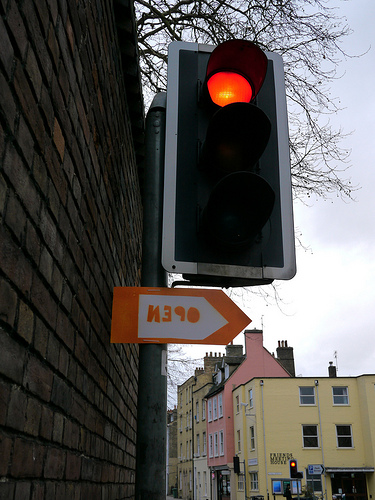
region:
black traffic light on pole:
[177, 35, 277, 257]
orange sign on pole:
[107, 285, 250, 343]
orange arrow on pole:
[106, 285, 254, 356]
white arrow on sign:
[120, 295, 233, 344]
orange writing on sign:
[144, 302, 208, 321]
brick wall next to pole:
[3, 302, 82, 409]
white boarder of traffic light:
[158, 166, 183, 268]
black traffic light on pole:
[288, 457, 297, 474]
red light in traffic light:
[217, 71, 251, 108]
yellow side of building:
[222, 381, 359, 494]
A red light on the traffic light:
[206, 68, 252, 104]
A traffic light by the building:
[289, 459, 298, 478]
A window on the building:
[298, 386, 314, 403]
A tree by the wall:
[137, 5, 370, 202]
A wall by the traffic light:
[0, 1, 166, 499]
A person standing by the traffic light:
[284, 484, 290, 499]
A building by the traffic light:
[234, 374, 372, 496]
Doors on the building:
[331, 474, 365, 499]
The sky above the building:
[134, 1, 373, 408]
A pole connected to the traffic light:
[137, 92, 165, 498]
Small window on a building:
[326, 383, 355, 410]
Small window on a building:
[330, 420, 357, 458]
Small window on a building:
[299, 413, 324, 451]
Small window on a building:
[290, 376, 329, 415]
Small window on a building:
[244, 383, 256, 409]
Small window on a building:
[244, 423, 259, 444]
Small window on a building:
[228, 391, 244, 410]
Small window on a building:
[233, 427, 249, 458]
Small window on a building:
[211, 393, 237, 433]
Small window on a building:
[191, 430, 207, 456]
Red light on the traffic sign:
[188, 37, 266, 107]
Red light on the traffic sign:
[285, 457, 297, 468]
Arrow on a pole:
[104, 275, 252, 350]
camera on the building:
[239, 396, 255, 419]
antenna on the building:
[329, 341, 342, 369]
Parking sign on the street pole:
[308, 461, 327, 476]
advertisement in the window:
[271, 476, 302, 491]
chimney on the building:
[274, 336, 297, 379]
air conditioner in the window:
[190, 412, 200, 421]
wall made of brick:
[15, 344, 45, 394]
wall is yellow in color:
[246, 386, 339, 422]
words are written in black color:
[270, 447, 289, 473]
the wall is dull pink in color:
[244, 355, 280, 370]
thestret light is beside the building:
[282, 446, 315, 484]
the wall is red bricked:
[44, 387, 126, 484]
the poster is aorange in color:
[129, 284, 243, 355]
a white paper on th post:
[158, 350, 179, 397]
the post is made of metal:
[140, 407, 166, 499]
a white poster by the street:
[310, 459, 328, 476]